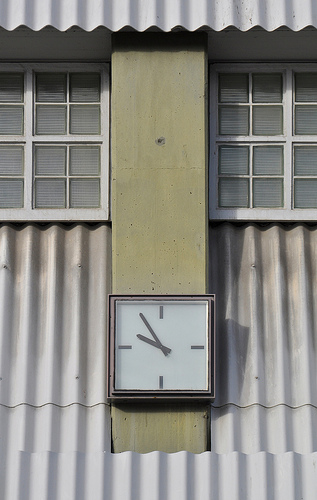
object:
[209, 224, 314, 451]
aluminum plates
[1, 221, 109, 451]
aluminum plates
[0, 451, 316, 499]
aluminum plates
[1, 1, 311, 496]
wall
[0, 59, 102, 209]
window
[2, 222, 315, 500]
tin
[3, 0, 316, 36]
siding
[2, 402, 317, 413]
siding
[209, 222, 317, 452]
panels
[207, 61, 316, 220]
window frame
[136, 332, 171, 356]
hand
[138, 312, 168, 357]
hand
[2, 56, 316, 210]
windows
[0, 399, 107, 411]
seam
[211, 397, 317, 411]
seam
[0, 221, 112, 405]
metal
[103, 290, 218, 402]
frame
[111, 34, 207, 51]
shadow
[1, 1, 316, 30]
roof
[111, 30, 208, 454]
cement pillar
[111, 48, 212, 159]
cement beam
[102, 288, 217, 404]
clock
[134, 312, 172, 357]
big hand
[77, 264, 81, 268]
screws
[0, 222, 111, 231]
tin siding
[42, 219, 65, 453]
ridges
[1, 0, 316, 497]
building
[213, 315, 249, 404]
shadow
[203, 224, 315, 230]
tin siding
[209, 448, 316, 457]
tin siding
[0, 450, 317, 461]
tin siding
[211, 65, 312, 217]
window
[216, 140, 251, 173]
glass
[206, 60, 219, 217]
frame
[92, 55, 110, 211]
frame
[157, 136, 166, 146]
hole